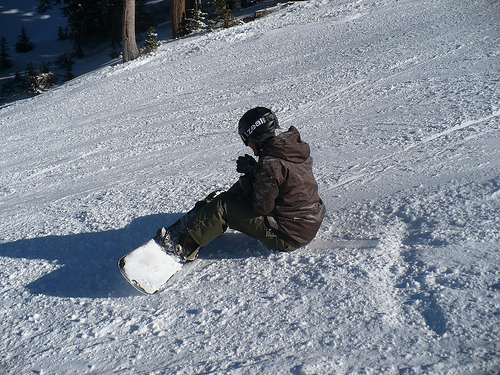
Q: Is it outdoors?
A: Yes, it is outdoors.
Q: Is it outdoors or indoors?
A: It is outdoors.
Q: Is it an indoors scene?
A: No, it is outdoors.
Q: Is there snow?
A: Yes, there is snow.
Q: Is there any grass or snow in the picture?
A: Yes, there is snow.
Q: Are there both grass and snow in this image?
A: No, there is snow but no grass.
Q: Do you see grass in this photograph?
A: No, there is no grass.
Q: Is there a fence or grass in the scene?
A: No, there are no grass or fences.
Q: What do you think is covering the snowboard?
A: The snow is covering the snowboard.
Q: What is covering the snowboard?
A: The snow is covering the snowboard.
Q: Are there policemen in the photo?
A: No, there are no policemen.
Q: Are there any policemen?
A: No, there are no policemen.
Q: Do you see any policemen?
A: No, there are no policemen.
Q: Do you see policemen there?
A: No, there are no policemen.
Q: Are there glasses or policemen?
A: No, there are no policemen or glasses.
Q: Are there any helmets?
A: Yes, there is a helmet.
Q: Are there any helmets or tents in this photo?
A: Yes, there is a helmet.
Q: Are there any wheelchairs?
A: No, there are no wheelchairs.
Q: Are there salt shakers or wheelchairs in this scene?
A: No, there are no wheelchairs or salt shakers.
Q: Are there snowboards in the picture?
A: Yes, there is a snowboard.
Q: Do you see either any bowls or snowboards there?
A: Yes, there is a snowboard.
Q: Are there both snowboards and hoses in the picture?
A: No, there is a snowboard but no hoses.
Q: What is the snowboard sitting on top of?
A: The snowboard is sitting on top of the snow.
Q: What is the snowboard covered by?
A: The snowboard is covered by the snow.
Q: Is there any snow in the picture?
A: Yes, there is snow.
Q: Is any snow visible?
A: Yes, there is snow.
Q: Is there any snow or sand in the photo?
A: Yes, there is snow.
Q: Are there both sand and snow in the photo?
A: No, there is snow but no sand.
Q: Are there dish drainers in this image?
A: No, there are no dish drainers.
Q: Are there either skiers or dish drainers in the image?
A: No, there are no dish drainers or skiers.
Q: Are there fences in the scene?
A: No, there are no fences.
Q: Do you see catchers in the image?
A: No, there are no catchers.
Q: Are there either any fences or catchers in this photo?
A: No, there are no catchers or fences.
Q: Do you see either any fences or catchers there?
A: No, there are no catchers or fences.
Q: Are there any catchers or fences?
A: No, there are no catchers or fences.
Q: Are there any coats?
A: Yes, there is a coat.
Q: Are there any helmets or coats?
A: Yes, there is a coat.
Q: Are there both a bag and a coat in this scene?
A: No, there is a coat but no bags.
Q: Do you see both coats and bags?
A: No, there is a coat but no bags.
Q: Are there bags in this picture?
A: No, there are no bags.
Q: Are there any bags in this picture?
A: No, there are no bags.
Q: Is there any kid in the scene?
A: No, there are no children.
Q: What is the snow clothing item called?
A: The clothing item is a snowsuit.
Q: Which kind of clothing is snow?
A: The clothing is a snowsuit.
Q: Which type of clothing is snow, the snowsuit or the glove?
A: The snowsuit is snow.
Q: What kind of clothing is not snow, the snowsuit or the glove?
A: The glove is not snow.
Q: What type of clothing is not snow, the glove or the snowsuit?
A: The glove is not snow.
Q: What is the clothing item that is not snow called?
A: The clothing item is a glove.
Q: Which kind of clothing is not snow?
A: The clothing is a glove.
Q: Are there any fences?
A: No, there are no fences.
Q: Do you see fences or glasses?
A: No, there are no fences or glasses.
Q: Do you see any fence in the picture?
A: No, there are no fences.